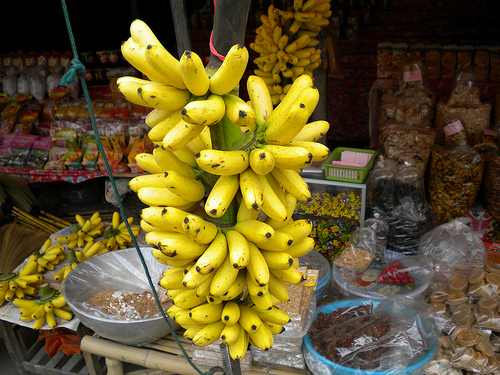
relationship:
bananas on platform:
[59, 230, 124, 253] [44, 273, 55, 283]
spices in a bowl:
[93, 289, 135, 319] [103, 322, 150, 344]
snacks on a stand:
[15, 107, 128, 165] [33, 170, 53, 177]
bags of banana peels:
[383, 84, 473, 195] [398, 136, 422, 161]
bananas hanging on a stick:
[120, 21, 325, 368] [208, 15, 251, 40]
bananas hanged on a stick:
[59, 230, 124, 253] [208, 15, 251, 40]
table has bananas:
[3, 308, 11, 323] [59, 230, 124, 253]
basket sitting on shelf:
[324, 165, 367, 182] [316, 177, 364, 193]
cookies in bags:
[446, 291, 493, 341] [383, 84, 473, 195]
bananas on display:
[59, 230, 124, 253] [56, 229, 75, 254]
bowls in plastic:
[312, 245, 432, 372] [359, 284, 395, 311]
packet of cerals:
[30, 100, 90, 128] [86, 91, 127, 120]